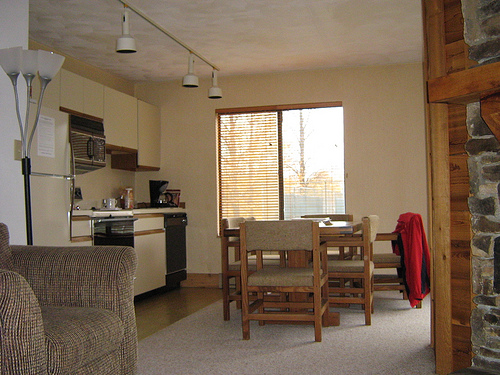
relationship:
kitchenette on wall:
[27, 96, 189, 304] [30, 37, 134, 304]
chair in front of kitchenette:
[0, 218, 139, 375] [27, 96, 189, 304]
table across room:
[221, 219, 366, 328] [1, 1, 499, 375]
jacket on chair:
[392, 213, 430, 308] [374, 210, 426, 310]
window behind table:
[216, 101, 348, 240] [221, 219, 366, 328]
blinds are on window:
[221, 106, 278, 220] [216, 101, 348, 240]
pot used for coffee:
[150, 180, 171, 207] [157, 200, 167, 204]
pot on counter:
[150, 180, 171, 207] [70, 206, 185, 217]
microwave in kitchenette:
[70, 131, 105, 168] [27, 96, 189, 304]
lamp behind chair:
[2, 45, 67, 246] [0, 218, 139, 375]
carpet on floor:
[137, 288, 431, 375] [135, 286, 435, 375]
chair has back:
[239, 220, 328, 343] [244, 222, 314, 251]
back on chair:
[244, 222, 314, 251] [239, 220, 328, 343]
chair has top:
[239, 220, 328, 343] [239, 219, 320, 277]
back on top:
[244, 222, 314, 251] [239, 219, 320, 277]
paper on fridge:
[35, 114, 59, 160] [27, 102, 77, 247]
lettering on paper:
[39, 117, 55, 157] [35, 114, 59, 160]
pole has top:
[21, 157, 36, 246] [20, 155, 32, 177]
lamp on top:
[0, 45, 67, 246] [20, 155, 32, 177]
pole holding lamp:
[21, 157, 36, 246] [0, 45, 67, 246]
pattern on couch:
[2, 318, 43, 375] [0, 218, 139, 375]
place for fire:
[466, 104, 498, 370] [493, 237, 500, 293]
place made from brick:
[466, 104, 498, 370] [467, 196, 498, 217]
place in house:
[466, 104, 498, 370] [1, 1, 499, 375]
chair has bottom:
[239, 220, 328, 343] [244, 276, 323, 342]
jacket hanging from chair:
[392, 213, 430, 308] [374, 210, 426, 310]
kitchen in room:
[31, 2, 239, 345] [1, 1, 499, 375]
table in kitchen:
[221, 219, 366, 328] [31, 2, 239, 345]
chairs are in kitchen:
[219, 213, 428, 344] [31, 2, 239, 345]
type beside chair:
[2, 45, 67, 246] [0, 218, 139, 375]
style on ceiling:
[111, 1, 225, 101] [30, 1, 425, 85]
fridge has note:
[27, 102, 77, 247] [35, 114, 59, 160]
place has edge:
[466, 104, 498, 370] [464, 103, 478, 373]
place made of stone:
[466, 104, 498, 370] [465, 135, 499, 157]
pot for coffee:
[150, 180, 171, 207] [157, 200, 167, 204]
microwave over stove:
[70, 131, 105, 168] [72, 205, 136, 248]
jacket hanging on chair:
[392, 213, 430, 308] [374, 210, 426, 310]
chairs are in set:
[219, 213, 428, 344] [217, 209, 428, 345]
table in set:
[221, 219, 366, 328] [217, 209, 428, 345]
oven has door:
[92, 215, 139, 248] [94, 219, 135, 248]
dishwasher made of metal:
[163, 213, 189, 290] [167, 229, 187, 275]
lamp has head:
[2, 45, 67, 246] [0, 46, 25, 161]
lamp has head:
[2, 45, 67, 246] [18, 49, 40, 159]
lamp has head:
[2, 45, 67, 246] [27, 50, 67, 158]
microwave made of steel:
[70, 131, 105, 168] [70, 114, 105, 173]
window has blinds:
[216, 101, 348, 240] [221, 106, 278, 220]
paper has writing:
[35, 114, 59, 160] [39, 117, 55, 157]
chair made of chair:
[0, 218, 139, 375] [239, 220, 328, 343]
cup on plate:
[104, 198, 119, 209] [101, 206, 125, 212]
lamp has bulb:
[2, 45, 67, 246] [0, 46, 23, 77]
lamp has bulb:
[2, 45, 67, 246] [20, 50, 40, 78]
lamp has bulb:
[2, 45, 67, 246] [35, 49, 64, 83]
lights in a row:
[114, 37, 225, 100] [117, 37, 225, 96]